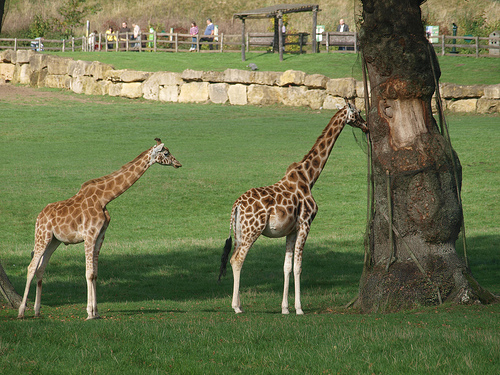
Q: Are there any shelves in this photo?
A: No, there are no shelves.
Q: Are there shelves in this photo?
A: No, there are no shelves.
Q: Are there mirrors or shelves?
A: No, there are no shelves or mirrors.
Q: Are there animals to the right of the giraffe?
A: Yes, there are animals to the right of the giraffe.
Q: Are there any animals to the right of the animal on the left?
A: Yes, there are animals to the right of the giraffe.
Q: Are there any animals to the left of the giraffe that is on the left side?
A: No, the animals are to the right of the giraffe.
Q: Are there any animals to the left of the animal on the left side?
A: No, the animals are to the right of the giraffe.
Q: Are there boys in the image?
A: No, there are no boys.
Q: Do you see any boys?
A: No, there are no boys.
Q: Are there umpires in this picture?
A: No, there are no umpires.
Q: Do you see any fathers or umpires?
A: No, there are no umpires or fathers.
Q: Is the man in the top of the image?
A: Yes, the man is in the top of the image.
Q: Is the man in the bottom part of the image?
A: No, the man is in the top of the image.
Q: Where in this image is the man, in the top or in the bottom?
A: The man is in the top of the image.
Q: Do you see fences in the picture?
A: Yes, there is a fence.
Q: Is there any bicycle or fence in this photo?
A: Yes, there is a fence.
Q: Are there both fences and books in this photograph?
A: No, there is a fence but no books.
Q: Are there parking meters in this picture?
A: No, there are no parking meters.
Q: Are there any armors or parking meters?
A: No, there are no parking meters or armors.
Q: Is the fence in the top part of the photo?
A: Yes, the fence is in the top of the image.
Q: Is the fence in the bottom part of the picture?
A: No, the fence is in the top of the image.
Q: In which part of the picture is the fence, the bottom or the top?
A: The fence is in the top of the image.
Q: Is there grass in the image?
A: Yes, there is grass.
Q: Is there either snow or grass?
A: Yes, there is grass.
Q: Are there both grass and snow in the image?
A: No, there is grass but no snow.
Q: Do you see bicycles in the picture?
A: No, there are no bicycles.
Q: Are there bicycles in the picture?
A: No, there are no bicycles.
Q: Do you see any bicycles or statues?
A: No, there are no bicycles or statues.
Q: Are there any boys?
A: No, there are no boys.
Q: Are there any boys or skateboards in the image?
A: No, there are no boys or skateboards.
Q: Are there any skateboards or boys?
A: No, there are no boys or skateboards.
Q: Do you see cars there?
A: No, there are no cars.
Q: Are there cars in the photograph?
A: No, there are no cars.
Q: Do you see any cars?
A: No, there are no cars.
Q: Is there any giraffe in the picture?
A: Yes, there is a giraffe.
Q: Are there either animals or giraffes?
A: Yes, there is a giraffe.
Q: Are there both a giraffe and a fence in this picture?
A: Yes, there are both a giraffe and a fence.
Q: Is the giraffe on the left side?
A: Yes, the giraffe is on the left of the image.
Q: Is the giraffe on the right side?
A: No, the giraffe is on the left of the image.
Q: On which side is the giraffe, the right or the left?
A: The giraffe is on the left of the image.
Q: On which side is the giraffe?
A: The giraffe is on the left of the image.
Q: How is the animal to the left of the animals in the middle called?
A: The animal is a giraffe.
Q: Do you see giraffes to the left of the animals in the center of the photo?
A: Yes, there is a giraffe to the left of the animals.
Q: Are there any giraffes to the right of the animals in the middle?
A: No, the giraffe is to the left of the animals.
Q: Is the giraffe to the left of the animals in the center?
A: Yes, the giraffe is to the left of the animals.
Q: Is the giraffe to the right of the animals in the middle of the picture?
A: No, the giraffe is to the left of the animals.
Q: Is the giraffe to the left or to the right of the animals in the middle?
A: The giraffe is to the left of the animals.